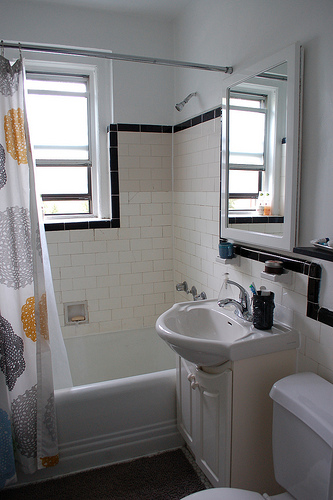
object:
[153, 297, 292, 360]
sink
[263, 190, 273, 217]
bathwash bottle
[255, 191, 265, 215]
bathwash bottle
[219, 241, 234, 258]
cup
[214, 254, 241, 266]
ledge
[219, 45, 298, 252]
frame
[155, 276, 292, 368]
kitchen sink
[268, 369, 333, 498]
toilet tank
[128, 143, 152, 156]
bathroom tiles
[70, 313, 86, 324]
soap holder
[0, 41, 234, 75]
rod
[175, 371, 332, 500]
toilet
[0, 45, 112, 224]
window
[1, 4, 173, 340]
wall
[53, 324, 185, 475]
tub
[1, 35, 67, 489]
curtain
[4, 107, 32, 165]
circle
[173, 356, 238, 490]
doors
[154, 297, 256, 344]
handwash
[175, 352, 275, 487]
cabinet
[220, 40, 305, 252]
cabinet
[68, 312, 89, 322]
soap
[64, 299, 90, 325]
dispenser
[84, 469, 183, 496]
rug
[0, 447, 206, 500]
floor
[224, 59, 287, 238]
mirror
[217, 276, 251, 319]
faucet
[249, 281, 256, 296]
toothbrushes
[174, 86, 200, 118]
shower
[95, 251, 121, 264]
tile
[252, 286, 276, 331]
cup